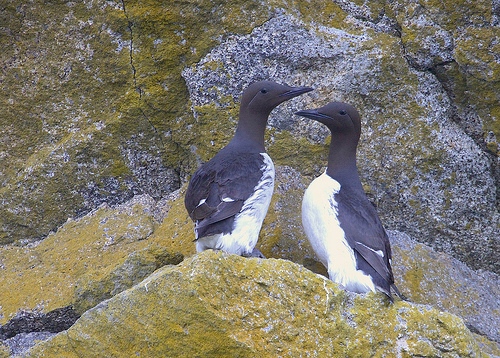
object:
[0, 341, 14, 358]
moss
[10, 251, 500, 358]
rock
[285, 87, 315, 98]
beak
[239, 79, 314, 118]
black head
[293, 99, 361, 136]
black head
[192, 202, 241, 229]
feather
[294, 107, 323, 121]
beak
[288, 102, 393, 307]
bird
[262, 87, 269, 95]
eyes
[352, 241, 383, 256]
white feathers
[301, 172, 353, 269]
chest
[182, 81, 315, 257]
bird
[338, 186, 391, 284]
wings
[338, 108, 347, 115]
black eyes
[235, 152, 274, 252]
chest